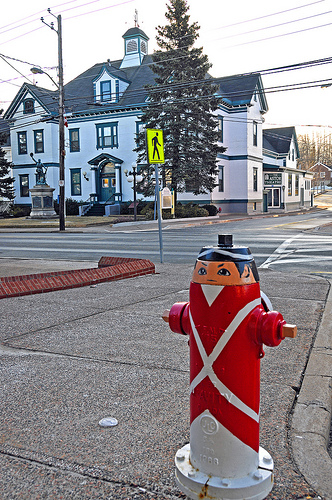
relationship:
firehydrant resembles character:
[160, 245, 295, 476] [184, 249, 263, 305]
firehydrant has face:
[160, 245, 295, 476] [184, 249, 276, 285]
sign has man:
[140, 123, 167, 174] [150, 134, 163, 162]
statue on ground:
[24, 144, 57, 219] [10, 208, 187, 245]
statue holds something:
[24, 144, 57, 219] [30, 148, 34, 160]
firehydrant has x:
[160, 245, 295, 476] [187, 314, 254, 432]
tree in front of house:
[142, 0, 224, 208] [7, 19, 266, 212]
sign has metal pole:
[140, 123, 167, 174] [151, 164, 169, 265]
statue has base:
[24, 144, 57, 219] [33, 189, 59, 219]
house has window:
[7, 19, 266, 212] [91, 119, 125, 150]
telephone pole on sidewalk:
[54, 17, 72, 233] [3, 223, 144, 237]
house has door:
[7, 19, 266, 212] [88, 162, 130, 201]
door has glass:
[88, 162, 130, 201] [101, 177, 119, 187]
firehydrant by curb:
[160, 245, 295, 476] [289, 267, 330, 500]